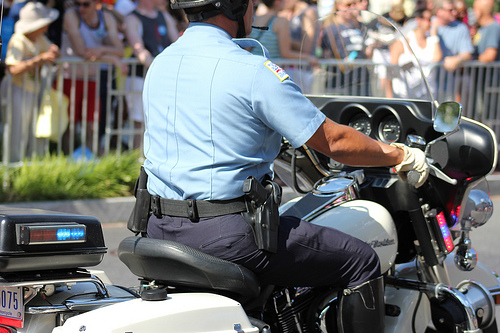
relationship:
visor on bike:
[298, 7, 437, 117] [0, 0, 499, 333]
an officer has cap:
[130, 0, 431, 333] [171, 0, 251, 16]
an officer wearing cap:
[130, 0, 431, 333] [171, 0, 251, 16]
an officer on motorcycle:
[130, 0, 431, 333] [37, 91, 474, 323]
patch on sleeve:
[264, 57, 292, 80] [223, 38, 330, 150]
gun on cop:
[242, 167, 284, 256] [122, 1, 397, 332]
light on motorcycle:
[5, 207, 103, 292] [1, 8, 498, 329]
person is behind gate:
[389, 15, 444, 99] [6, 52, 498, 167]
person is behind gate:
[321, 2, 376, 94] [6, 52, 498, 167]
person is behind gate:
[464, 2, 498, 62] [6, 52, 498, 167]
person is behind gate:
[435, 3, 473, 109] [6, 52, 498, 167]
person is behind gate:
[119, 2, 195, 140] [6, 52, 498, 167]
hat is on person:
[9, 4, 91, 43] [9, 7, 105, 209]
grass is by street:
[3, 150, 145, 203] [2, 194, 499, 329]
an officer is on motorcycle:
[130, 0, 431, 333] [1, 8, 498, 329]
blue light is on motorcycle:
[51, 225, 88, 244] [1, 8, 498, 329]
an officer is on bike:
[130, 0, 431, 333] [1, 74, 496, 331]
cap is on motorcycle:
[126, 0, 428, 330] [1, 8, 498, 329]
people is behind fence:
[318, 4, 478, 56] [92, 54, 447, 99]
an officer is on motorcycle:
[130, 0, 431, 333] [14, 102, 490, 330]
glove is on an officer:
[388, 138, 430, 188] [130, 0, 431, 333]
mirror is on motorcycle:
[425, 99, 467, 131] [1, 8, 498, 329]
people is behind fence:
[1, 2, 62, 162] [1, 55, 498, 169]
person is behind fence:
[61, 0, 131, 157] [1, 55, 498, 169]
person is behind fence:
[123, 2, 196, 122] [1, 55, 498, 169]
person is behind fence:
[321, 2, 376, 94] [1, 55, 498, 169]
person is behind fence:
[389, 15, 444, 99] [1, 55, 498, 169]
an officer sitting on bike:
[130, 0, 431, 333] [62, 8, 494, 331]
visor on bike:
[298, 7, 437, 117] [1, 8, 499, 331]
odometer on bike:
[361, 87, 412, 151] [1, 8, 499, 331]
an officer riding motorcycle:
[130, 0, 431, 333] [1, 8, 498, 329]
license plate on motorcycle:
[2, 282, 24, 319] [1, 8, 498, 329]